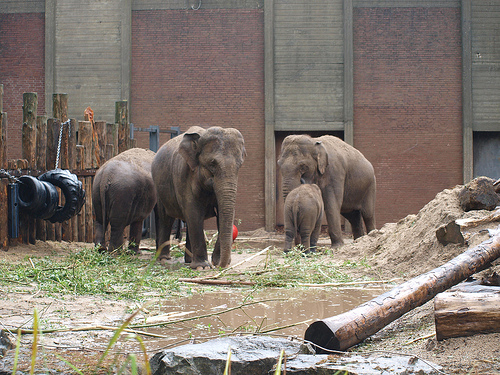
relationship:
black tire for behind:
[11, 175, 40, 208] [277, 134, 377, 248]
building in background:
[186, 20, 491, 152] [2, 1, 499, 232]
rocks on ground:
[150, 332, 320, 374] [0, 227, 497, 372]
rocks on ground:
[271, 350, 446, 372] [0, 227, 497, 372]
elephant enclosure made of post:
[5, 92, 194, 252] [111, 97, 131, 123]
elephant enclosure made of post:
[5, 92, 194, 252] [58, 92, 71, 129]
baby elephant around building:
[284, 184, 325, 254] [0, 0, 497, 220]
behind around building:
[277, 134, 377, 248] [0, 0, 497, 220]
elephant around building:
[150, 122, 245, 275] [0, 0, 497, 220]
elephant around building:
[95, 145, 154, 252] [0, 0, 497, 220]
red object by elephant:
[231, 222, 240, 247] [150, 122, 245, 275]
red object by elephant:
[231, 222, 240, 247] [85, 145, 163, 264]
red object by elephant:
[231, 222, 240, 247] [280, 177, 325, 253]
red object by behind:
[231, 222, 240, 247] [277, 134, 377, 248]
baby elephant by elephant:
[284, 184, 325, 254] [271, 125, 383, 242]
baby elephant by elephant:
[284, 184, 325, 254] [152, 120, 253, 267]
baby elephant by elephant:
[284, 184, 325, 254] [89, 142, 159, 249]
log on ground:
[310, 233, 452, 356] [420, 332, 468, 368]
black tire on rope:
[12, 175, 41, 212] [2, 120, 68, 184]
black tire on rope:
[28, 178, 58, 220] [2, 120, 68, 184]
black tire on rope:
[36, 169, 84, 224] [2, 120, 68, 184]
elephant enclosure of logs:
[5, 92, 194, 252] [24, 88, 37, 167]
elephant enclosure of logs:
[5, 92, 194, 252] [55, 91, 67, 168]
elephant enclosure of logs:
[5, 92, 194, 252] [118, 98, 133, 148]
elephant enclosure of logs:
[5, 92, 194, 252] [0, 109, 9, 246]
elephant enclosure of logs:
[5, 92, 194, 252] [81, 116, 91, 243]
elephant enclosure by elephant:
[5, 92, 194, 252] [280, 177, 325, 253]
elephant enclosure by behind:
[5, 92, 194, 252] [277, 134, 377, 248]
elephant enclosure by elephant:
[5, 92, 194, 252] [150, 122, 245, 275]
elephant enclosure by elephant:
[5, 92, 194, 252] [90, 143, 155, 253]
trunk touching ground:
[196, 143, 249, 290] [4, 178, 499, 370]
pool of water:
[3, 276, 386, 373] [168, 245, 455, 352]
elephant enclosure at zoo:
[3, 1, 498, 373] [4, 3, 498, 372]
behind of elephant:
[281, 194, 317, 234] [281, 178, 323, 255]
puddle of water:
[6, 281, 390, 371] [4, 284, 395, 373]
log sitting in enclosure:
[302, 227, 499, 350] [2, 88, 497, 373]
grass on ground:
[36, 250, 316, 321] [2, 241, 499, 367]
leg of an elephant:
[181, 203, 215, 261] [149, 112, 253, 277]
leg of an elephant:
[153, 209, 168, 260] [150, 122, 245, 275]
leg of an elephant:
[107, 213, 129, 252] [89, 142, 159, 249]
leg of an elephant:
[175, 214, 210, 262] [128, 92, 271, 293]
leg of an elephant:
[181, 203, 215, 261] [89, 142, 159, 249]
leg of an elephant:
[280, 226, 294, 254] [150, 122, 245, 275]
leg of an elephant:
[359, 209, 379, 234] [280, 184, 322, 251]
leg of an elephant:
[181, 203, 215, 261] [278, 131, 375, 201]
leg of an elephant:
[185, 219, 213, 271] [150, 122, 245, 275]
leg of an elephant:
[323, 188, 344, 248] [280, 177, 325, 253]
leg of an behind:
[360, 202, 375, 235] [277, 134, 377, 248]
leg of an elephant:
[341, 210, 365, 239] [150, 122, 245, 275]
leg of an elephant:
[181, 214, 208, 268] [92, 146, 159, 254]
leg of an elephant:
[322, 185, 345, 250] [150, 122, 245, 275]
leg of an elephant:
[363, 181, 380, 234] [88, 145, 151, 258]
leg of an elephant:
[181, 203, 215, 261] [280, 177, 325, 253]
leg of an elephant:
[282, 225, 294, 254] [281, 133, 376, 188]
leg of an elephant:
[156, 206, 175, 254] [281, 133, 376, 188]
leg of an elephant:
[353, 187, 388, 235] [271, 125, 383, 242]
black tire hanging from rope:
[37, 169, 85, 223] [2, 117, 70, 182]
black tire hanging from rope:
[11, 175, 40, 208] [2, 117, 70, 182]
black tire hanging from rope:
[28, 180, 59, 220] [2, 117, 70, 182]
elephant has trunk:
[150, 126, 248, 271] [209, 168, 240, 270]